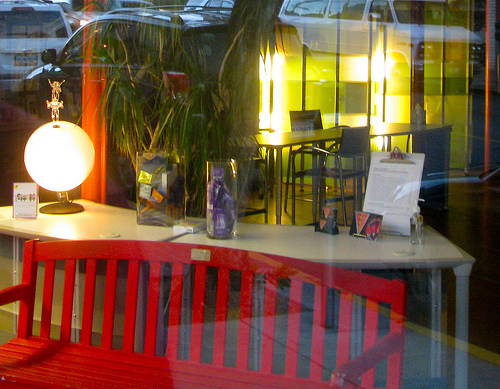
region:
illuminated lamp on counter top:
[15, 102, 105, 202]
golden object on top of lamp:
[42, 78, 65, 120]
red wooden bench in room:
[15, 248, 419, 388]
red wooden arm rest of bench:
[324, 330, 404, 387]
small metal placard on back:
[180, 245, 217, 265]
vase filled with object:
[200, 153, 247, 236]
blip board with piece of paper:
[346, 146, 422, 236]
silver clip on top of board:
[377, 152, 413, 166]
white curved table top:
[183, 217, 463, 291]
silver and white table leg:
[446, 263, 469, 388]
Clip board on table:
[359, 140, 426, 242]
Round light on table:
[15, 111, 101, 222]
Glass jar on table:
[198, 149, 250, 245]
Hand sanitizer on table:
[402, 193, 436, 249]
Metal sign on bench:
[188, 246, 218, 266]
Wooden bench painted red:
[88, 357, 161, 382]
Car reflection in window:
[15, 3, 325, 151]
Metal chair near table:
[293, 121, 377, 199]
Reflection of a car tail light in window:
[157, 61, 198, 117]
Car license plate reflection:
[11, 49, 43, 71]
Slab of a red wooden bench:
[36, 243, 55, 348]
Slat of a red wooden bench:
[59, 253, 81, 372]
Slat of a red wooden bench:
[73, 254, 104, 354]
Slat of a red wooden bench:
[102, 256, 122, 361]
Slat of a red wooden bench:
[115, 256, 137, 351]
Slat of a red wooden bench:
[139, 253, 166, 356]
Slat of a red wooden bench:
[165, 250, 189, 367]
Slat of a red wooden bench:
[182, 258, 207, 373]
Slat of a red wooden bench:
[207, 259, 235, 374]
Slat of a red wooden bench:
[232, 264, 257, 386]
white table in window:
[430, 251, 486, 306]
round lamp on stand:
[16, 126, 109, 211]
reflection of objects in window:
[166, 247, 292, 343]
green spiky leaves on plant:
[126, 90, 224, 135]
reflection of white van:
[309, 13, 472, 117]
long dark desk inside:
[272, 125, 280, 147]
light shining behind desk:
[368, 94, 415, 144]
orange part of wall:
[91, 31, 124, 201]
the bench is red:
[27, 238, 362, 386]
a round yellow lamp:
[14, 100, 122, 216]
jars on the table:
[202, 151, 252, 247]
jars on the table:
[115, 131, 193, 236]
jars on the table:
[186, 146, 247, 267]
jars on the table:
[103, 128, 215, 259]